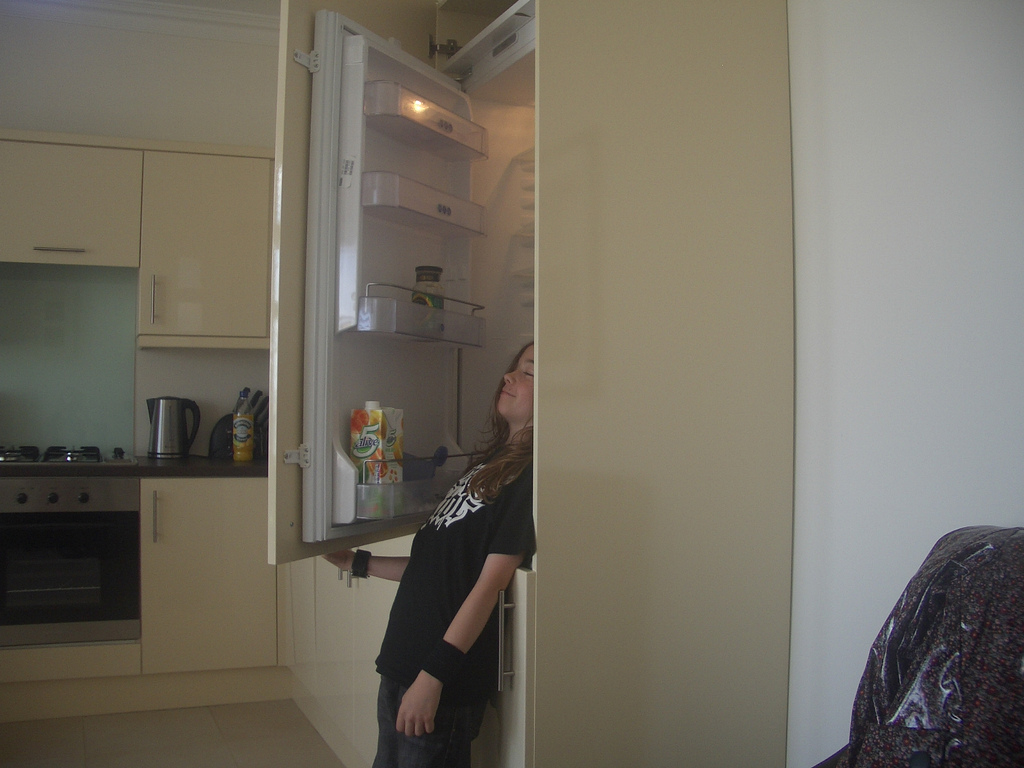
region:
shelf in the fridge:
[409, 105, 499, 144]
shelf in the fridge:
[364, 155, 491, 238]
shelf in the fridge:
[374, 446, 445, 523]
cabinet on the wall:
[150, 473, 265, 673]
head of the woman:
[479, 364, 527, 419]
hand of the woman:
[384, 685, 441, 737]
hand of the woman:
[285, 533, 366, 562]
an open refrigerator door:
[297, 13, 469, 546]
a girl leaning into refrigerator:
[313, 332, 535, 766]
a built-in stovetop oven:
[5, 445, 139, 646]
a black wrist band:
[424, 638, 462, 678]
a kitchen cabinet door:
[2, 142, 142, 270]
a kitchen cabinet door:
[135, 151, 273, 339]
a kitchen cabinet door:
[138, 478, 279, 671]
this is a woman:
[307, 306, 584, 759]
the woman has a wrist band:
[418, 625, 540, 730]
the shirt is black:
[368, 446, 528, 732]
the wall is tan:
[582, 162, 766, 706]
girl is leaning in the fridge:
[323, 304, 562, 766]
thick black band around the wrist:
[413, 632, 480, 681]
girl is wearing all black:
[331, 303, 567, 766]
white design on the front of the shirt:
[413, 457, 512, 556]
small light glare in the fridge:
[399, 93, 439, 119]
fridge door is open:
[263, 4, 548, 596]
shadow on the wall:
[7, 263, 93, 344]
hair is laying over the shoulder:
[466, 434, 539, 492]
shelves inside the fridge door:
[340, 52, 486, 337]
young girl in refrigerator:
[386, 338, 564, 756]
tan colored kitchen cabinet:
[23, 151, 134, 276]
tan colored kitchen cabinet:
[141, 144, 268, 335]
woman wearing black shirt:
[340, 320, 549, 750]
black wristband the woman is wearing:
[419, 636, 458, 684]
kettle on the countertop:
[144, 386, 208, 460]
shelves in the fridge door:
[363, 76, 491, 514]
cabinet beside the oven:
[142, 478, 264, 672]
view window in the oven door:
[5, 546, 108, 610]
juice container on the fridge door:
[335, 386, 403, 513]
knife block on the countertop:
[205, 389, 263, 465]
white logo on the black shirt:
[410, 445, 487, 522]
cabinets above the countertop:
[9, 137, 265, 356]